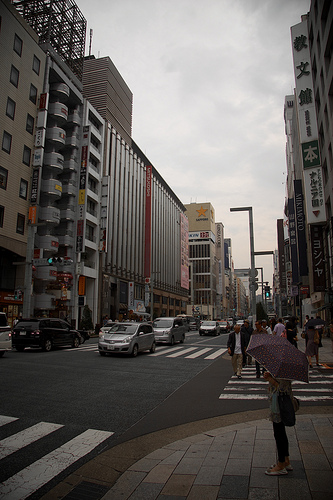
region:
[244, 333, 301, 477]
woman standing on the sidewalk with an umbrella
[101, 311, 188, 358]
two silver cars on the street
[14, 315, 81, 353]
black van driving down the street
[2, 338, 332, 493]
white lines painted on the road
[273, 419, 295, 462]
black pants worn by woman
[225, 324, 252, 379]
man wearing sport coat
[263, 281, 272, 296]
traffic signal showing green light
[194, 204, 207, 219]
yellow star on side of building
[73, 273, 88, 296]
orange and black sign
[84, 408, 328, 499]
sidewalk woman with umbrella is standing on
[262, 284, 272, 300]
Traffic light is green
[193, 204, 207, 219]
Orange star on building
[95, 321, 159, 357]
Silver vehicle on the street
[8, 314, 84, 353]
Black vehicle on the street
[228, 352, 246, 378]
Man wearing khaki pants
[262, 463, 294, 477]
Woman wearing flat shoes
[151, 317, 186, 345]
Silver SUV on the street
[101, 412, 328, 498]
Walkway is made of stone tiles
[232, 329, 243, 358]
Man wearing a white shirt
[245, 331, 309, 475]
Woman holding a purple umbrella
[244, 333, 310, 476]
Person holding a purple umbrella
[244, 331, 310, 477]
Person obfuscated by an umbrella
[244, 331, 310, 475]
Woman obfuscated by an umbrella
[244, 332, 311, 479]
Person obfuscated by a purple umbrella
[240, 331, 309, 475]
Person standing on a sidewalk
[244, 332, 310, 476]
Person standing on a sidewalk with an umbrella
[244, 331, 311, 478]
Person standing on a sidewalk with a purple umbrella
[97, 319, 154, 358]
Silver car driving on the street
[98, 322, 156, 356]
Silver colored car on the street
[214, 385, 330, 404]
white line in street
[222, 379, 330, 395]
white line in street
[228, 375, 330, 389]
white line in street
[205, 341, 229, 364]
white line in street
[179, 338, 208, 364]
white line in street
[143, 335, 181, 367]
white line in street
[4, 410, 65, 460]
white line in street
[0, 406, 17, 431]
white line in street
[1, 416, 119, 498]
white line in street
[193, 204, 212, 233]
red star on beige building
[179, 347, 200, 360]
big white lines on street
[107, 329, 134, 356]
small silver car on street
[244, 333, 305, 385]
woman holding patterned umbrella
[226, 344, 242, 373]
man wearing beige pants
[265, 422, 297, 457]
woman wearing black pants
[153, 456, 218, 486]
gray and red bricks on ground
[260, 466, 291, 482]
woman wearing white and black shoes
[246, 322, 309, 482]
A person standing on the corner of the sidewalk.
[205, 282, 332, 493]
People walking on the sidewalk.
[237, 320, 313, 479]
A person standing under an umbrella.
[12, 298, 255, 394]
Vehicles on the road.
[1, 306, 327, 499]
The road.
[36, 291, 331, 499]
the sidewalk.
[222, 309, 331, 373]
pedestrians crossing the road.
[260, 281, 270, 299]
A pedestrian crosswalk signal.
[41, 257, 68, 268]
A traffic light hanging over the road.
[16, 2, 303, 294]
A grey and white sky.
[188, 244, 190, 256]
a window on a building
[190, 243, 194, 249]
a window on a building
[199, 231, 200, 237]
a window on a building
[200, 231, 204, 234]
a window on a building